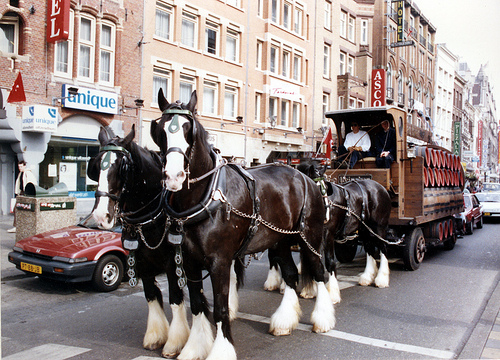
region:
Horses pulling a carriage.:
[90, 100, 485, 358]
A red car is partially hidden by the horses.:
[0, 205, 140, 285]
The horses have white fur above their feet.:
[135, 295, 245, 355]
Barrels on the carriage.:
[411, 131, 476, 191]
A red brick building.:
[0, 6, 140, 231]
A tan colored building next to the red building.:
[140, 0, 310, 136]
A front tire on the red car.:
[92, 247, 122, 287]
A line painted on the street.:
[340, 325, 485, 355]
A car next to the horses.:
[5, 115, 425, 350]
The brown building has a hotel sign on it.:
[376, 0, 436, 120]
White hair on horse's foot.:
[312, 287, 346, 357]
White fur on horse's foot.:
[258, 311, 298, 346]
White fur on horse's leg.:
[211, 304, 231, 356]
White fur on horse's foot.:
[181, 328, 201, 347]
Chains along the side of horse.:
[210, 174, 350, 269]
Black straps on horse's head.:
[151, 96, 208, 153]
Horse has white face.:
[160, 112, 195, 209]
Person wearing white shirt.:
[329, 130, 359, 155]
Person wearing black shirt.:
[373, 130, 391, 148]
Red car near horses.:
[35, 222, 110, 272]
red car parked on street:
[3, 207, 122, 288]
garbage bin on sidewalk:
[11, 181, 74, 243]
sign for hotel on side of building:
[393, 2, 415, 48]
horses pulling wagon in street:
[88, 102, 383, 359]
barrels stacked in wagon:
[412, 147, 469, 189]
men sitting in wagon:
[341, 118, 396, 163]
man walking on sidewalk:
[10, 157, 32, 237]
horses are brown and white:
[92, 90, 392, 359]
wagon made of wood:
[326, 110, 465, 225]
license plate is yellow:
[16, 255, 47, 275]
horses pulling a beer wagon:
[86, 79, 486, 334]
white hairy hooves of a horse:
[258, 282, 369, 349]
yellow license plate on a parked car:
[12, 256, 52, 278]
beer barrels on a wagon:
[416, 140, 467, 188]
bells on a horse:
[168, 247, 190, 299]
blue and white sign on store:
[63, 82, 120, 117]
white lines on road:
[338, 325, 457, 355]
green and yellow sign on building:
[393, 1, 410, 45]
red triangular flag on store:
[5, 67, 32, 107]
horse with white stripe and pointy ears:
[147, 81, 212, 213]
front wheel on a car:
[86, 251, 128, 296]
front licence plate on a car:
[15, 258, 46, 275]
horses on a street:
[79, 80, 401, 358]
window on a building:
[219, 78, 243, 130]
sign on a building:
[384, 0, 415, 50]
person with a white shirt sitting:
[333, 118, 375, 168]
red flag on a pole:
[318, 122, 338, 160]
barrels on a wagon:
[406, 141, 470, 211]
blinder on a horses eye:
[146, 113, 166, 147]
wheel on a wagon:
[399, 221, 433, 274]